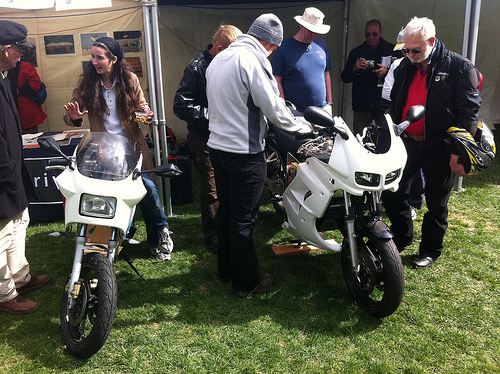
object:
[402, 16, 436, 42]
hair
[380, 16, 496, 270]
man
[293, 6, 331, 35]
hat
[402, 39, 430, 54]
sunglasses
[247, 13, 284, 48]
cap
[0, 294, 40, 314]
shoe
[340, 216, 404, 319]
wheel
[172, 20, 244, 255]
person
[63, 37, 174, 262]
girl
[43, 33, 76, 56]
picture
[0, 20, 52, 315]
guy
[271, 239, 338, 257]
wood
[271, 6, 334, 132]
man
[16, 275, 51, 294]
shoes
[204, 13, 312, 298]
man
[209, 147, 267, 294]
pants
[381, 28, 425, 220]
man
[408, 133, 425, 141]
belt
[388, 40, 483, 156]
coat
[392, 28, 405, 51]
shades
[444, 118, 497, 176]
helmet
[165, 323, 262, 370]
grass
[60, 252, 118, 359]
wheel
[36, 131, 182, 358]
bike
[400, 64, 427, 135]
shirt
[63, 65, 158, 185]
coat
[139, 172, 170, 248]
jeans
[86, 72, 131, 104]
scarf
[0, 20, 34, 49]
hat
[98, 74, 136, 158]
shirt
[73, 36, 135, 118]
hair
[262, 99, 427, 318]
motorcycle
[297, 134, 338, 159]
part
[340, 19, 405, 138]
guy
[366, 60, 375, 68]
camera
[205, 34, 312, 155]
jacket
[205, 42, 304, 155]
stripe